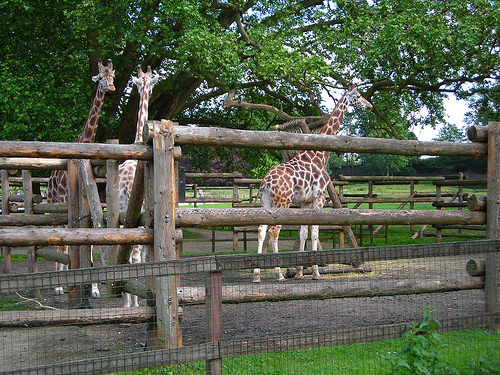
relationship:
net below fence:
[1, 238, 500, 374] [1, 122, 497, 363]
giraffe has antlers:
[57, 56, 115, 205] [96, 54, 111, 68]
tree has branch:
[4, 1, 500, 159] [215, 3, 257, 23]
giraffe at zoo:
[258, 86, 371, 277] [1, 122, 497, 363]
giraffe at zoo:
[258, 86, 371, 277] [4, 0, 492, 373]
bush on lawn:
[377, 312, 442, 373] [185, 323, 494, 368]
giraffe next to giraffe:
[112, 64, 166, 213] [57, 56, 115, 205]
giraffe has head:
[112, 64, 166, 213] [127, 62, 162, 92]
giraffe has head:
[57, 56, 115, 205] [91, 59, 122, 94]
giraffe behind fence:
[258, 86, 371, 277] [1, 122, 497, 363]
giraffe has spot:
[258, 86, 371, 277] [309, 167, 321, 179]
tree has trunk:
[4, 1, 500, 159] [95, 109, 140, 141]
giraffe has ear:
[57, 56, 115, 205] [89, 73, 103, 84]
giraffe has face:
[57, 56, 115, 205] [101, 72, 112, 90]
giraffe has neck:
[258, 86, 371, 277] [319, 99, 349, 136]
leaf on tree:
[109, 8, 120, 13] [4, 1, 500, 159]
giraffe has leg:
[258, 86, 371, 277] [256, 198, 266, 283]